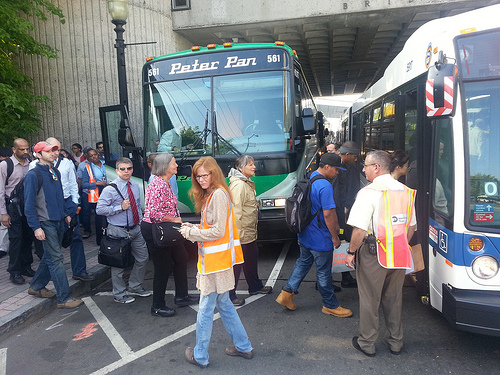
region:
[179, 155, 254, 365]
A woman wearing a bright orange vest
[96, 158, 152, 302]
A man holding a messenger bag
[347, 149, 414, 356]
A man wearing a red vest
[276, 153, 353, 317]
A man with a black backpack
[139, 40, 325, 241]
A bus with a green front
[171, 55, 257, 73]
The name Peter Pan on front of the bus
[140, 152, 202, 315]
An older lady walking towards a bus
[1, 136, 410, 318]
A group of people getting on a bus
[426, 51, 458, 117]
The side rearview mirror of a bus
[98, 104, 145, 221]
The door of a bus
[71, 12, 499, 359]
people in a bus station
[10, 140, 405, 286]
they are queing for a bus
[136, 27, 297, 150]
the bus is green in colour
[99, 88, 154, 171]
the door is open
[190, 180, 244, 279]
the lady has a reflective jacket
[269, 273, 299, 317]
the shoes are brown in colour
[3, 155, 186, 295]
everyone is carrying a bag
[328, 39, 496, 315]
the bus is white in colour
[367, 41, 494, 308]
the bus is stripped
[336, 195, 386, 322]
the man has a walkie talkie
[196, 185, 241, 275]
Reflective vest worn by woman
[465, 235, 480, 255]
Orange turn signal on the bus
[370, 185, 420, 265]
Red reflective vest worn by man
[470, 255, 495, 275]
Headlight on the bus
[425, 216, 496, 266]
Blue strip on the side of the bus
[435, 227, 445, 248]
Blue handicap sticker on side of bus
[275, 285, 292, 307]
Brown boot worn by man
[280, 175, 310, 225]
Black backpack being worn my man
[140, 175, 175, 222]
Floral shirt worn by older woman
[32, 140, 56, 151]
Red hat worn by man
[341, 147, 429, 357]
A man standing by the bus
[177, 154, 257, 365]
A woman in an orange vest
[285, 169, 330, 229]
A backpack on a man's back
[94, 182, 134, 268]
A black soft side briefcase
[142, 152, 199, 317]
A woman in a colorful shirt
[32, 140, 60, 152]
A red baseball cap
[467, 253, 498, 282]
The front right headlight on a bus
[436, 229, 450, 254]
A handicap symbol on the bus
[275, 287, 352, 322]
A man's brown boots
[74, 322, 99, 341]
Red paint on the street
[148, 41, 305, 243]
green and black bus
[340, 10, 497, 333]
white and blue bus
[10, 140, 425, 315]
people boarding the white and blue bus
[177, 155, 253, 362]
woman with the orange vest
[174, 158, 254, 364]
red headed woman with glasses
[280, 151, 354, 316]
man in work boots with black backpack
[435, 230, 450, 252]
handicap symbol on the front of blue white bus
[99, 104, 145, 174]
open door on the green bus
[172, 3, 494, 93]
bridge over the busses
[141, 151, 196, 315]
older woman with the red floral shirt